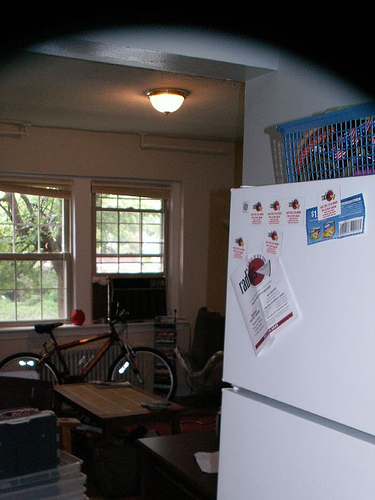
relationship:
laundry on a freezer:
[276, 103, 375, 185] [216, 172, 375, 500]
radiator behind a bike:
[41, 347, 144, 385] [1, 309, 176, 400]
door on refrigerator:
[216, 383, 371, 497] [208, 174, 373, 498]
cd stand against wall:
[155, 316, 179, 397] [0, 163, 238, 400]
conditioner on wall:
[93, 260, 171, 320] [0, 105, 209, 402]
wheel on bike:
[0, 350, 65, 415] [1, 309, 176, 400]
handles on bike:
[92, 298, 133, 326] [1, 297, 182, 420]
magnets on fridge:
[235, 189, 341, 247] [214, 177, 362, 410]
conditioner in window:
[92, 272, 167, 321] [98, 265, 184, 330]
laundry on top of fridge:
[275, 110, 372, 179] [225, 171, 372, 488]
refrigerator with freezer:
[208, 174, 373, 498] [217, 170, 373, 441]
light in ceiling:
[114, 85, 238, 134] [0, 47, 239, 139]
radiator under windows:
[41, 347, 142, 384] [0, 180, 175, 325]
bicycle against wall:
[2, 293, 181, 405] [0, 126, 227, 389]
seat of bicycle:
[18, 309, 62, 335] [0, 277, 184, 418]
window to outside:
[2, 184, 72, 322] [96, 191, 165, 268]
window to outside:
[91, 184, 162, 270] [2, 188, 62, 316]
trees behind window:
[3, 181, 68, 321] [1, 171, 76, 331]